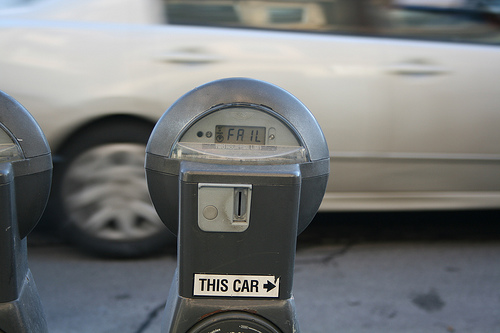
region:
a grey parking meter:
[145, 79, 334, 330]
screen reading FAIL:
[208, 120, 267, 147]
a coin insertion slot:
[194, 179, 250, 233]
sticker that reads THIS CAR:
[188, 274, 279, 301]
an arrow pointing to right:
[260, 279, 277, 295]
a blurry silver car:
[5, 0, 489, 253]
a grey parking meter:
[0, 91, 55, 330]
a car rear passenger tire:
[43, 119, 188, 264]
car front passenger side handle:
[378, 53, 456, 91]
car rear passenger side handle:
[142, 45, 220, 68]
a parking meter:
[161, 81, 336, 331]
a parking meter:
[200, 114, 281, 314]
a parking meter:
[217, 191, 285, 328]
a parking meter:
[180, 172, 252, 326]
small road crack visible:
[308, 241, 370, 286]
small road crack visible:
[322, 217, 392, 287]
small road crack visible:
[298, 210, 367, 301]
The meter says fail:
[216, 125, 269, 145]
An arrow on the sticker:
[261, 279, 276, 299]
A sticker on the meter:
[180, 267, 290, 309]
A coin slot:
[225, 187, 259, 224]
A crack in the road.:
[120, 284, 165, 331]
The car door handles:
[165, 37, 455, 82]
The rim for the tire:
[71, 145, 153, 245]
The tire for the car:
[52, 101, 182, 270]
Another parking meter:
[2, 74, 69, 330]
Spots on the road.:
[379, 259, 469, 331]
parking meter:
[126, 63, 377, 330]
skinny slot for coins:
[234, 188, 246, 218]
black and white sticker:
[191, 260, 289, 306]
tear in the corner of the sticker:
[272, 273, 282, 285]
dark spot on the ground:
[411, 283, 449, 312]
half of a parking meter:
[1, 96, 71, 328]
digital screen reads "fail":
[218, 125, 265, 145]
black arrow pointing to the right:
[260, 273, 277, 297]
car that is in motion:
[0, 1, 498, 273]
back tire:
[51, 121, 190, 256]